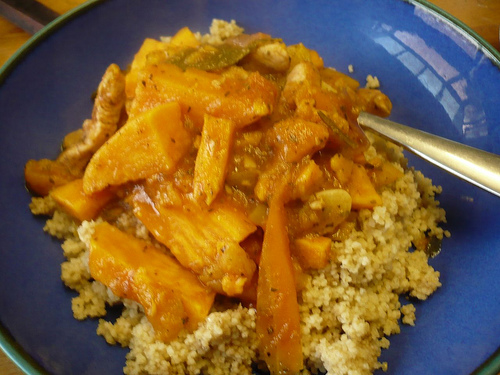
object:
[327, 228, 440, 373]
grain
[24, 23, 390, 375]
chicken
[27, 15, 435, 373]
cous cous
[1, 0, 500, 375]
blue plate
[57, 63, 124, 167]
ginger root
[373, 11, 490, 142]
light reflection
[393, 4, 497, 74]
trim